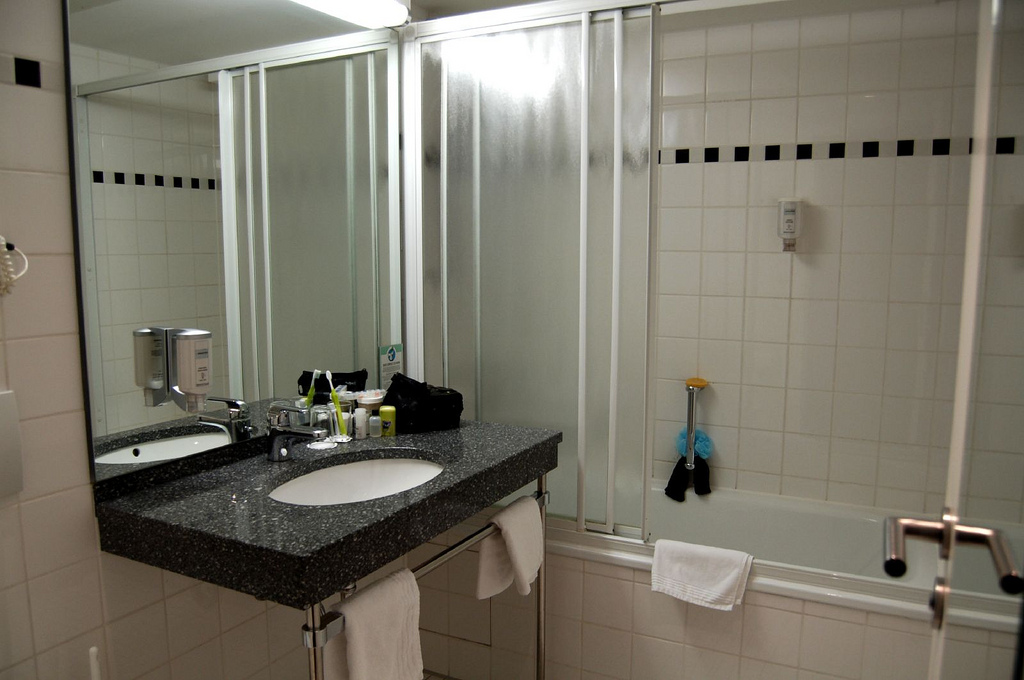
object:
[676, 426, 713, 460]
puff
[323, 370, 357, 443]
toothbrush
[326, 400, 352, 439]
cup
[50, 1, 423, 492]
bad mirror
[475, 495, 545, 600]
cloth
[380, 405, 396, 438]
personal items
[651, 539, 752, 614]
towel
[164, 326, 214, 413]
dispenser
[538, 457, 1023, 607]
bathtub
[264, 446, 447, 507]
sink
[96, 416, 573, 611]
counter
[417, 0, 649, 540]
doors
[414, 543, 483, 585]
bar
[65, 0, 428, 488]
mirror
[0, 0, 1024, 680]
bathroom